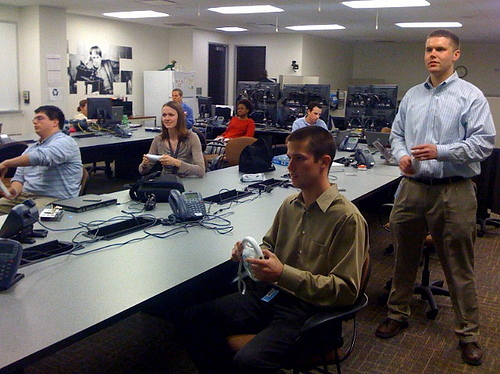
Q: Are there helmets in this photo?
A: No, there are no helmets.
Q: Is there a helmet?
A: No, there are no helmets.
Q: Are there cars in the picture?
A: No, there are no cars.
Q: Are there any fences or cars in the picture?
A: No, there are no cars or fences.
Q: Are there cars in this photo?
A: No, there are no cars.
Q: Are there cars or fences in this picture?
A: No, there are no cars or fences.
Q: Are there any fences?
A: No, there are no fences.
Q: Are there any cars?
A: No, there are no cars.